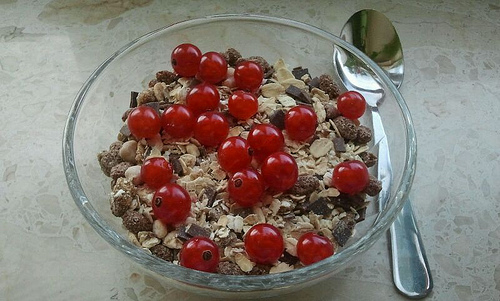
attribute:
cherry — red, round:
[130, 108, 157, 140]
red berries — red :
[217, 123, 296, 207]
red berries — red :
[127, 82, 228, 146]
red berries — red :
[333, 160, 368, 194]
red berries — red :
[141, 157, 191, 222]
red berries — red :
[228, 62, 265, 120]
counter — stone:
[399, 61, 499, 201]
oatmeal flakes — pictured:
[97, 48, 381, 273]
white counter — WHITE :
[1, 4, 498, 295]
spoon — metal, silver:
[333, 7, 435, 298]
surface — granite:
[0, 0, 499, 300]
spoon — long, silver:
[318, 19, 451, 299]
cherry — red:
[331, 152, 377, 191]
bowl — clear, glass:
[62, 10, 419, 299]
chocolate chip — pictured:
[182, 220, 214, 240]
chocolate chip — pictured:
[294, 170, 318, 199]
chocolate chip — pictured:
[280, 79, 314, 104]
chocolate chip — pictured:
[145, 96, 166, 114]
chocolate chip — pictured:
[289, 57, 311, 79]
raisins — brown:
[150, 241, 181, 260]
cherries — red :
[167, 31, 297, 206]